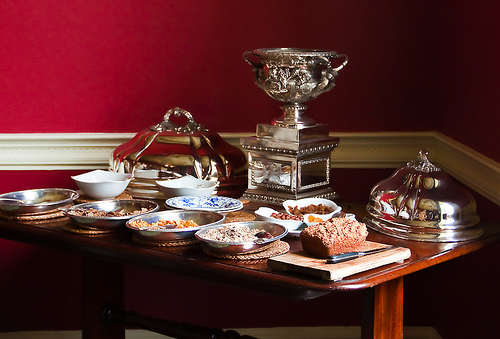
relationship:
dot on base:
[255, 145, 260, 151] [236, 123, 338, 207]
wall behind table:
[2, 1, 455, 155] [8, 165, 466, 280]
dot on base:
[238, 148, 312, 193] [235, 134, 336, 207]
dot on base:
[287, 148, 292, 153] [244, 139, 338, 209]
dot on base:
[250, 145, 256, 149] [244, 139, 338, 209]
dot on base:
[270, 147, 275, 151] [244, 139, 338, 209]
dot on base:
[309, 147, 313, 152] [244, 139, 338, 209]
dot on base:
[330, 144, 334, 147] [244, 139, 338, 209]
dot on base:
[255, 143, 265, 153] [241, 136, 337, 205]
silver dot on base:
[242, 188, 272, 210] [233, 174, 365, 210]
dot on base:
[295, 147, 304, 155] [229, 115, 341, 206]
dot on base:
[302, 144, 311, 154] [242, 139, 335, 203]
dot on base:
[312, 145, 316, 151] [252, 124, 323, 204]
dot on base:
[332, 190, 338, 195] [232, 185, 342, 212]